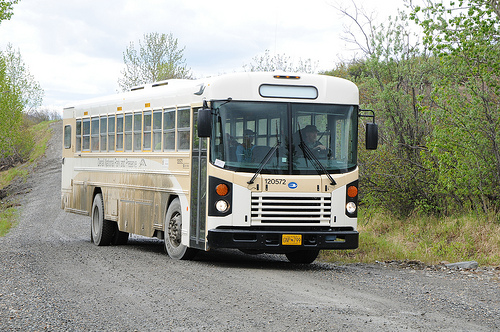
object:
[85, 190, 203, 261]
wheels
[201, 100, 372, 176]
window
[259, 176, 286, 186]
number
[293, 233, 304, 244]
number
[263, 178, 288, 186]
120572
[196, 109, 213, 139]
mirror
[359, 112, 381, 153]
mirror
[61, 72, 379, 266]
bus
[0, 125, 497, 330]
road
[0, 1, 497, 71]
sky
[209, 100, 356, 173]
windshield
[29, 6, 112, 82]
partly cloudy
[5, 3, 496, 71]
sky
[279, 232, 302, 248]
license plate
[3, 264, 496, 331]
road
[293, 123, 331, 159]
driver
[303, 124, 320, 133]
hat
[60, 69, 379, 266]
white bus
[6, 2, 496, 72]
clouds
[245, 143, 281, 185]
windshield wiper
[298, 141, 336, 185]
windshield wiper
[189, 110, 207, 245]
double doors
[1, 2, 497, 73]
clouds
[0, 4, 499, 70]
cloud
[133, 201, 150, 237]
mud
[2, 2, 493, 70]
clouds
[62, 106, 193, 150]
passenger